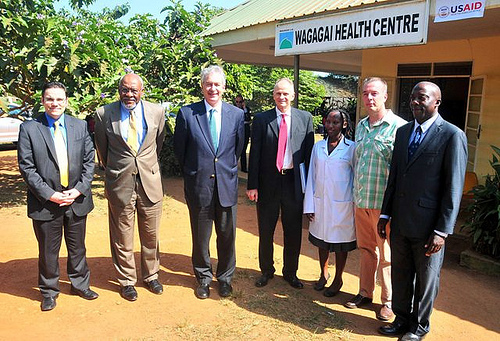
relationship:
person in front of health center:
[376, 77, 471, 337] [198, 26, 499, 252]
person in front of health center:
[353, 73, 409, 334] [198, 26, 499, 252]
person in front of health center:
[304, 104, 359, 299] [198, 26, 499, 252]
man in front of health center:
[245, 74, 317, 290] [198, 26, 499, 252]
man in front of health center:
[170, 65, 247, 300] [198, 26, 499, 252]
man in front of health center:
[93, 70, 170, 303] [198, 26, 499, 252]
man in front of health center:
[14, 79, 99, 312] [198, 26, 499, 252]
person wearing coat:
[298, 104, 359, 299] [302, 132, 355, 242]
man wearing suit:
[93, 70, 170, 303] [106, 101, 166, 288]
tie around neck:
[274, 112, 291, 175] [267, 96, 297, 114]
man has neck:
[245, 74, 317, 290] [267, 96, 297, 114]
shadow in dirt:
[220, 285, 392, 339] [1, 179, 498, 333]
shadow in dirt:
[0, 248, 392, 339] [1, 179, 498, 333]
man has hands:
[17, 86, 107, 307] [41, 185, 84, 207]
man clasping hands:
[17, 86, 107, 307] [41, 185, 84, 207]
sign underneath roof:
[268, 0, 433, 58] [199, 0, 499, 76]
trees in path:
[1, 1, 216, 113] [2, 142, 499, 340]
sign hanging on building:
[264, 7, 434, 64] [194, 0, 498, 290]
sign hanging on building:
[433, 0, 492, 24] [194, 0, 498, 290]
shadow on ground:
[0, 248, 392, 339] [106, 292, 204, 339]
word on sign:
[332, 16, 372, 41] [255, 11, 454, 53]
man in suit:
[17, 71, 99, 316] [16, 109, 99, 299]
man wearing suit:
[14, 79, 99, 316] [19, 115, 96, 300]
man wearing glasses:
[17, 71, 99, 316] [39, 95, 68, 105]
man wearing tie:
[170, 67, 247, 300] [206, 104, 218, 150]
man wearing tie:
[259, 78, 316, 280] [274, 112, 292, 169]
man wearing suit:
[17, 71, 99, 316] [384, 118, 466, 338]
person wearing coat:
[298, 104, 359, 299] [301, 128, 358, 246]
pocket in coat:
[328, 192, 357, 240] [305, 130, 362, 258]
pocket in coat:
[306, 191, 325, 226] [305, 130, 362, 258]